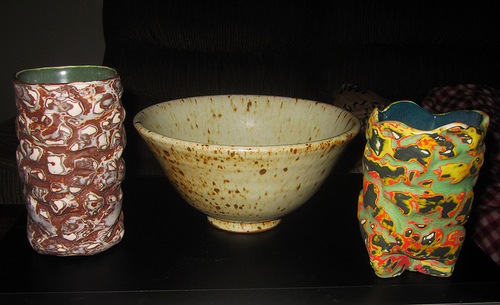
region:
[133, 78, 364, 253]
brown and white bowl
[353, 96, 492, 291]
multi-colored green vase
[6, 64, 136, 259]
brown and white cup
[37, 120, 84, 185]
swirl marks on side of brown and white cup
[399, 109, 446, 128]
green interior of green and yellow cup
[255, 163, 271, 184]
brown spot on surface of bowl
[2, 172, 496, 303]
black table surface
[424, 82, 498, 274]
checkered pattern on fabric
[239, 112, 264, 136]
white light reflected on inner surface of bowl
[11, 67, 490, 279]
three stone ware pieces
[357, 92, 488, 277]
yellow and sreens with dark green interior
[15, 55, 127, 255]
swirled brown and white with green interior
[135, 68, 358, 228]
a grey stone ware bowl with brown spots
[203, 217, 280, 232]
bowl is made with a flat pedestal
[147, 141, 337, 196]
the lines are visible that was made by shaping on a potters wheel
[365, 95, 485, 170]
a wavy top to this peice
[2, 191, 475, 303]
the pottery sits on a black table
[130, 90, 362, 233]
Deep bowl with brown speckles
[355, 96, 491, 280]
Colorful ceramic vase with dark green interior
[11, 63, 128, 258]
Brown and white vase with green interior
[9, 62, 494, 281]
Two vases and a bowl sitting on a table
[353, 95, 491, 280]
Textured vase with colorful splotches on pale green background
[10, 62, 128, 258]
Vase with texture like rock wall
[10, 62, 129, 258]
Vase with rusty brown and white swirls and splotches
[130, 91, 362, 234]
Cream colored bowl with rusty brown spots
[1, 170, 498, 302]
Rectangular black table top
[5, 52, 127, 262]
THIS IS THE TALLER VASE OF THE TWO IN THE PHOTO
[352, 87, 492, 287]
THE VASE IS COLORFUL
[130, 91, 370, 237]
THE BOWL IS DEEP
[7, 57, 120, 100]
THE INSIDE OF THE VASE IS GREEN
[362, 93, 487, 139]
THE INSIDE OF THE VASE IS BLUE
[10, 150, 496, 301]
THE TABLE IS BLACK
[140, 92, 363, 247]
THE BOWL IS BIG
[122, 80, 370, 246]
THE BOWL IS BEIGE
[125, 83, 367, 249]
THE BOWL HAS BROWN SPOTS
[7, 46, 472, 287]
pottery pieces side by side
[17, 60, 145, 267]
reddish pot on the left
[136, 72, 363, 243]
bowl in the middle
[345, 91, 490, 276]
pot on the right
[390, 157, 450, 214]
pattern on pot on right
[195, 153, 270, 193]
pattern on middle bowl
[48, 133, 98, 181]
pattern on pot on left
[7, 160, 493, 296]
black table that pottery rests on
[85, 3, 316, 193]
chair behind the pots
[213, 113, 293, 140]
interior of the bowl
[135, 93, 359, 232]
the bowl has brown spots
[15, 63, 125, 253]
the vase is brown and white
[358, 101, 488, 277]
the inside of the vase is dark blue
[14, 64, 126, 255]
the inside of the vase is dark green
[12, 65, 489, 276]
the bowl in the middle of the two vases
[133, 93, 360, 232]
the bowl is empty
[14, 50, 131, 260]
red and white cup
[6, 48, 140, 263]
red and white cup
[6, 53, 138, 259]
red and white cup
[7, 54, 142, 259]
red and white cup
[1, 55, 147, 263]
red and white cup